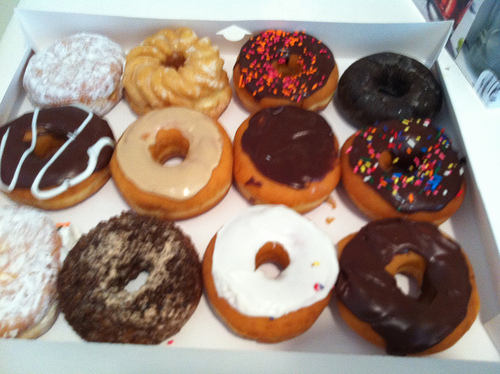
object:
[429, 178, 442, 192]
sprinkles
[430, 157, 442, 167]
sprinkles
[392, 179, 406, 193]
sprinkles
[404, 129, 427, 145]
sprinkles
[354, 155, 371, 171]
sprinkles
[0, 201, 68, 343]
sugar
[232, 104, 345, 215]
donut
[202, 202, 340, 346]
donut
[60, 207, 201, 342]
round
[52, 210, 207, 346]
chocolate doughnut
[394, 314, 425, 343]
chocolate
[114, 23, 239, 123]
cruller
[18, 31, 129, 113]
donut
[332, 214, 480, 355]
doughnut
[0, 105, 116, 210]
doughnut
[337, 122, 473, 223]
donut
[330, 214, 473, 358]
frosting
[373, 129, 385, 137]
sprinkles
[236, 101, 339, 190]
frosting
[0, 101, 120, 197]
frosting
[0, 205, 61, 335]
powder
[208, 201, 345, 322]
frosted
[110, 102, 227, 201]
frosting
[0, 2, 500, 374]
box